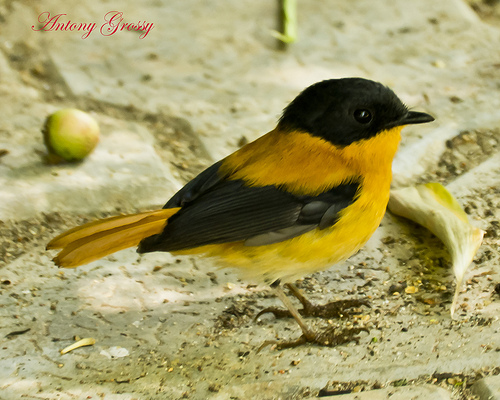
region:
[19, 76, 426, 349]
a bird on the ground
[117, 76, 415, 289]
a small bird on the ground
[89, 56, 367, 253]
a yellow and black bird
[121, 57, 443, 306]
a small yellow and black bird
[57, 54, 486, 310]
a bird that is small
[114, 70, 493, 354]
a bird that is yellow and black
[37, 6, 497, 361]
a bird standing on a rcok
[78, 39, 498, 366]
a small bird standing outside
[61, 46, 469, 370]
a bird that is standing outside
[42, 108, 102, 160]
a round fruit on the ground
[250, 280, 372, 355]
small brown bird feet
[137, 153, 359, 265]
black bird feathers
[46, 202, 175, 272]
a yellow tail feather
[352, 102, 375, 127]
a beady black eye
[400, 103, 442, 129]
a short black beak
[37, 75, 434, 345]
a black and yellow bird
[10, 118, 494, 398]
bird seed on the ground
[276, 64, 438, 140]
head of a bird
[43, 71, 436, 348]
small bird standing on gro und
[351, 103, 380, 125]
eye of small standing bird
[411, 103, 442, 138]
beak of small standing bird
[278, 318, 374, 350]
foot of small standing bird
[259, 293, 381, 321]
foot of small standing bird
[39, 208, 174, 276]
tail feathers of small standing bird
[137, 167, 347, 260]
wing feathers of small standing bird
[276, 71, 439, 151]
head of small standing bird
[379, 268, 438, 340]
rocky area under bird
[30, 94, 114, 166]
seed near small bird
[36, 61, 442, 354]
bird standing in dirt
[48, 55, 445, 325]
bird is yellow and black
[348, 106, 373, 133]
birds eye is black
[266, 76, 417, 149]
birds head is black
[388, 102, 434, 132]
birds beak is black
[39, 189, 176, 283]
birds tail is yellow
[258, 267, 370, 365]
birds leg is brown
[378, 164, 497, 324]
banana peel in front of bird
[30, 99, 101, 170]
apple on dirt in background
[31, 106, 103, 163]
apple is not ripe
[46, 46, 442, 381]
a small bird on the ground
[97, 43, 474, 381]
a blakc and yellow bird on the ground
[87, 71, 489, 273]
a bird standing outside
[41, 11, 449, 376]
a small bird standing on the ground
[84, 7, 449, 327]
a bird standing on the ground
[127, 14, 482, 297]
a bird that is outside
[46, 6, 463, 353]
a bird that is standing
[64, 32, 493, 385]
a bird that is black and white